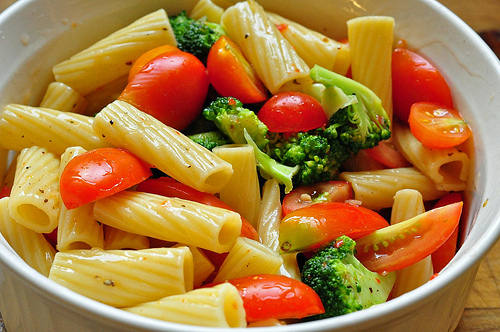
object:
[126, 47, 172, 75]
tomatoes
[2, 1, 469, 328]
pasta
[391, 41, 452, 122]
tomatoes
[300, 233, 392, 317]
broccoli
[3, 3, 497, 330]
bowl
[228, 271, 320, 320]
tomato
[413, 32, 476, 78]
sauce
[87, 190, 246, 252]
noodle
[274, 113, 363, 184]
broccoli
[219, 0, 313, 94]
noodles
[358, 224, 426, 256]
seeds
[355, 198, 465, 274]
tomato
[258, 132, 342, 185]
broccoli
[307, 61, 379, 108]
stem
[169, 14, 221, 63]
broccoli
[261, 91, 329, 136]
tomato half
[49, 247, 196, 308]
noodle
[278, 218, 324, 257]
tip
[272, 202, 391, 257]
tomato half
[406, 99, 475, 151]
tomato half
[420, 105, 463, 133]
seeds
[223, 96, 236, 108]
pepper flake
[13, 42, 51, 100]
dressing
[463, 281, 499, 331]
counter top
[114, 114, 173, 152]
ridges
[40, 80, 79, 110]
rigatoni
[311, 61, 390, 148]
broccoli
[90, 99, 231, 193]
noodle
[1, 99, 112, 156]
noodle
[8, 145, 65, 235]
noodle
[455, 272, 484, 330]
table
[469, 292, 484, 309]
spot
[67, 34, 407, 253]
salad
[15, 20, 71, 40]
crumbs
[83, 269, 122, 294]
seasoning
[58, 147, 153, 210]
tomato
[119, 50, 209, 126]
tomato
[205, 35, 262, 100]
tomato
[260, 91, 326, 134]
tomato